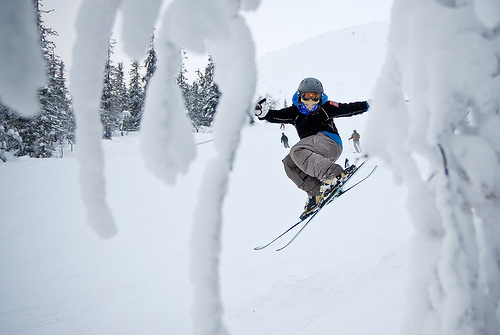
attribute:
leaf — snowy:
[364, 4, 497, 329]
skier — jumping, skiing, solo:
[254, 74, 373, 215]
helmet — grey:
[294, 75, 324, 103]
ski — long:
[252, 165, 379, 252]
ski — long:
[275, 158, 368, 254]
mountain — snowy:
[2, 1, 498, 330]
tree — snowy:
[99, 30, 123, 140]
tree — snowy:
[111, 61, 129, 134]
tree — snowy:
[143, 27, 156, 88]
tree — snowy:
[29, 0, 61, 132]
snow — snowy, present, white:
[0, 125, 427, 333]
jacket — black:
[268, 99, 368, 136]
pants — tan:
[280, 132, 345, 200]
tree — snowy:
[198, 55, 220, 128]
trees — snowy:
[1, 1, 220, 160]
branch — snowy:
[144, 51, 153, 67]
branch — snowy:
[49, 123, 65, 135]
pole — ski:
[348, 139, 354, 154]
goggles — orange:
[302, 92, 321, 102]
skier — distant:
[277, 132, 291, 150]